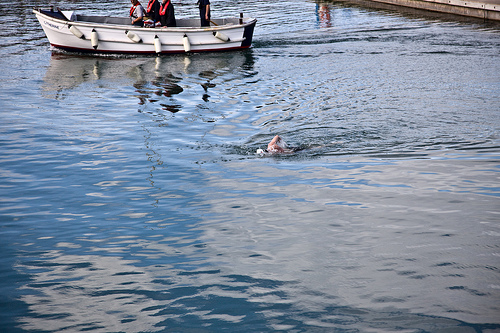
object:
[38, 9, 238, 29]
deck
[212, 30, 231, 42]
gunport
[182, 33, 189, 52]
gunport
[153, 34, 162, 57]
gunport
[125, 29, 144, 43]
gunport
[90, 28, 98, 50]
gunport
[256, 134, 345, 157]
man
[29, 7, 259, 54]
boat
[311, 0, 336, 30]
reflection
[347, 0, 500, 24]
dock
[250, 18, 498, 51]
trail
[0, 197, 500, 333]
waves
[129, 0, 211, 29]
people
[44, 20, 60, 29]
writing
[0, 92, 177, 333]
zebras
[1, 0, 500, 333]
water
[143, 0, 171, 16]
vest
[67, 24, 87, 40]
buoy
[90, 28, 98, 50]
buoy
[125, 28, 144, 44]
buoy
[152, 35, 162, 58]
buoy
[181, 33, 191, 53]
buoy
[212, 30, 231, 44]
buoy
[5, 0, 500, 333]
reflection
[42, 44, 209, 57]
wale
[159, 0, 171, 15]
life preserver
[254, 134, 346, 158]
object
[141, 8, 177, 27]
clothing